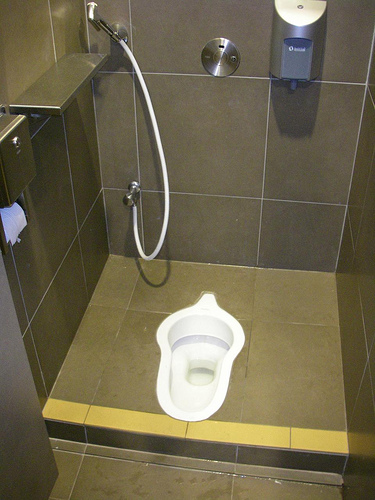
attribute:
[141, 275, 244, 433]
toilet — white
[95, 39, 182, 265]
hose — metal, white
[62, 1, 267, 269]
wall — tiled, tile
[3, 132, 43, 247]
toilet paper — white, on roll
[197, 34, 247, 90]
flush button — round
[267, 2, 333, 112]
hand sanitizer — silver, gray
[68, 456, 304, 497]
floor — tiled, tile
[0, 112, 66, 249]
dispenser — for soap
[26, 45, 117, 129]
shelf — metal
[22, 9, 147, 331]
walls — brown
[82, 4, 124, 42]
handle — silver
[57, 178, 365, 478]
bathroom — unusual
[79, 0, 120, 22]
shower head — silver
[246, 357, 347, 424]
tile — brown